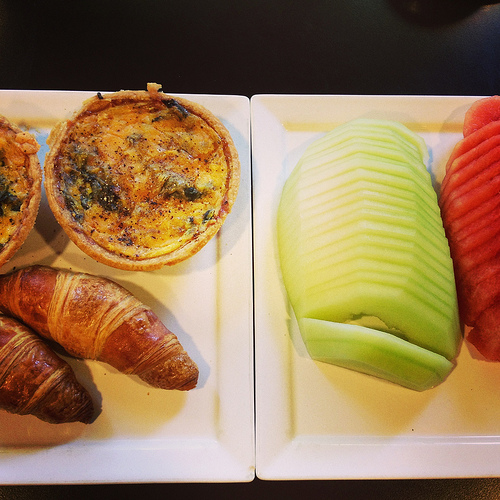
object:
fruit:
[276, 119, 461, 392]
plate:
[248, 92, 499, 487]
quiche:
[46, 92, 239, 273]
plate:
[1, 86, 256, 487]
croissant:
[0, 265, 199, 391]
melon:
[436, 92, 500, 362]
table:
[2, 0, 499, 499]